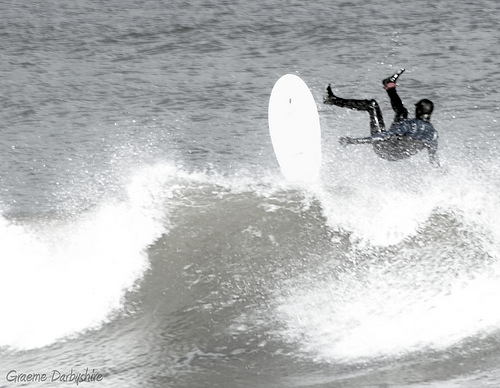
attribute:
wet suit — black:
[330, 86, 437, 161]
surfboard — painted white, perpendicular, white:
[266, 73, 320, 189]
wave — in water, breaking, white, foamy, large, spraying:
[2, 156, 498, 364]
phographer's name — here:
[4, 368, 101, 385]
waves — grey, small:
[0, 1, 497, 172]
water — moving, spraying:
[1, 1, 499, 387]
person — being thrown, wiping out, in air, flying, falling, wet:
[324, 68, 443, 170]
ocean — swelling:
[1, 2, 498, 387]